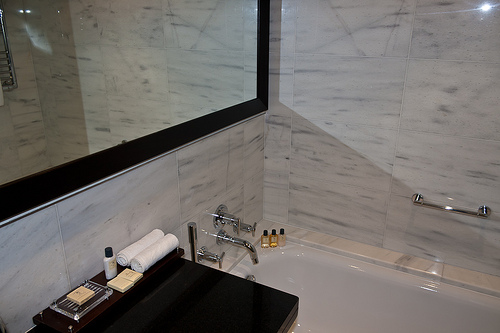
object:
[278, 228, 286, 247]
bottle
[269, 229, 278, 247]
bottle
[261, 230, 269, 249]
bottle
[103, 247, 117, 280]
bottle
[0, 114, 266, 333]
tiles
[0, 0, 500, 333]
bathroom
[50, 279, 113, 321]
box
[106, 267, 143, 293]
soap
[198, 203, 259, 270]
fixtures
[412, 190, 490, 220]
bar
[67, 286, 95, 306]
soap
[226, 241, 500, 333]
bath tub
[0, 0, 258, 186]
mirror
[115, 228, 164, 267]
hand towel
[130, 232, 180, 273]
hand towel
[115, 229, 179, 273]
two towels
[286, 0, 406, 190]
marble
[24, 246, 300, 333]
counter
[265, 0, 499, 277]
tiles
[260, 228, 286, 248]
soap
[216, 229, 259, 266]
faucet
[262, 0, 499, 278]
wall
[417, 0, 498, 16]
reflection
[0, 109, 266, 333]
wall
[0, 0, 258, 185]
reflection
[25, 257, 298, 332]
sink